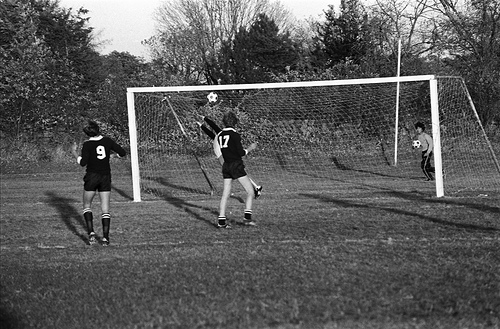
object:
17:
[219, 135, 230, 148]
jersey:
[218, 130, 246, 161]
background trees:
[0, 0, 500, 162]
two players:
[70, 113, 257, 246]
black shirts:
[80, 130, 246, 170]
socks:
[218, 210, 252, 225]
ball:
[412, 140, 421, 149]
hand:
[424, 153, 429, 157]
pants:
[421, 149, 435, 180]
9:
[96, 146, 107, 160]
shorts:
[222, 159, 247, 179]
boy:
[412, 123, 435, 182]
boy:
[213, 112, 254, 229]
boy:
[71, 122, 126, 246]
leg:
[220, 178, 233, 216]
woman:
[71, 120, 125, 246]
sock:
[83, 208, 94, 234]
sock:
[102, 213, 111, 240]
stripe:
[83, 208, 92, 214]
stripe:
[102, 214, 111, 219]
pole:
[429, 80, 444, 198]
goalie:
[196, 114, 263, 200]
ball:
[207, 92, 218, 103]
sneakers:
[88, 232, 109, 247]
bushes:
[1, 29, 108, 129]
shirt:
[80, 136, 126, 173]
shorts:
[83, 172, 111, 192]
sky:
[55, 0, 500, 62]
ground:
[0, 160, 500, 328]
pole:
[126, 92, 141, 202]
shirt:
[201, 116, 222, 140]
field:
[5, 152, 497, 327]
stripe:
[424, 155, 432, 180]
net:
[134, 76, 500, 199]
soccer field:
[0, 170, 500, 329]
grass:
[0, 174, 500, 329]